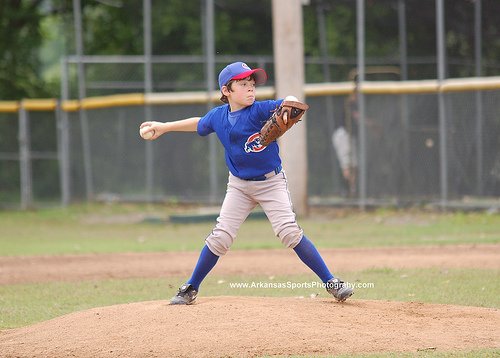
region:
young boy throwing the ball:
[115, 45, 380, 319]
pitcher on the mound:
[123, 58, 373, 318]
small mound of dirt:
[2, 293, 493, 353]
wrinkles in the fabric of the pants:
[276, 221, 304, 249]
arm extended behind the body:
[133, 109, 230, 154]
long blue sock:
[292, 234, 339, 284]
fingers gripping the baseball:
[127, 115, 164, 147]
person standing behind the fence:
[334, 122, 369, 202]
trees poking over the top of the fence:
[3, 1, 90, 100]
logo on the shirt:
[244, 126, 267, 158]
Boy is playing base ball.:
[35, 51, 457, 347]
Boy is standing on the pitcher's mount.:
[10, 45, 450, 351]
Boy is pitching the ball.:
[130, 115, 160, 145]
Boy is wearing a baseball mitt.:
[255, 85, 325, 150]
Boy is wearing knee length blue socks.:
[180, 235, 338, 290]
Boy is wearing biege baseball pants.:
[203, 170, 303, 252]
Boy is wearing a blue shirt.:
[196, 105, 292, 181]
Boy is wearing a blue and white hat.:
[210, 60, 267, 111]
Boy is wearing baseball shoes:
[165, 276, 355, 311]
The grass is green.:
[15, 287, 93, 307]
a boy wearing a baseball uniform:
[94, 51, 381, 317]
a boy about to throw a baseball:
[128, 60, 362, 304]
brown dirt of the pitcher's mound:
[58, 297, 480, 357]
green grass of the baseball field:
[28, 263, 142, 330]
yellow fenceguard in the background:
[16, 86, 486, 108]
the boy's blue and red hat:
[185, 54, 276, 93]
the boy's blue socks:
[149, 238, 356, 278]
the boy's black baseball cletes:
[130, 266, 377, 306]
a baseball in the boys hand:
[128, 112, 175, 149]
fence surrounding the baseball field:
[1, 3, 495, 67]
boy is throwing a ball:
[105, 26, 296, 134]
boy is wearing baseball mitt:
[251, 95, 326, 165]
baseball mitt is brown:
[255, 90, 320, 150]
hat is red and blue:
[202, 37, 273, 87]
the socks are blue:
[175, 215, 386, 300]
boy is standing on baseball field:
[107, 40, 428, 307]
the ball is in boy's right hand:
[125, 107, 180, 157]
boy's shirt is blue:
[188, 105, 293, 173]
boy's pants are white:
[196, 162, 310, 241]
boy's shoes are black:
[143, 256, 383, 312]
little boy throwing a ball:
[121, 53, 359, 310]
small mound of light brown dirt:
[8, 289, 486, 350]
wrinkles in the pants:
[274, 216, 299, 239]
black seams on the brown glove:
[258, 124, 275, 144]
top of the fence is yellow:
[0, 72, 499, 114]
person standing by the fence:
[328, 111, 368, 197]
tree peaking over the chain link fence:
[1, 3, 65, 95]